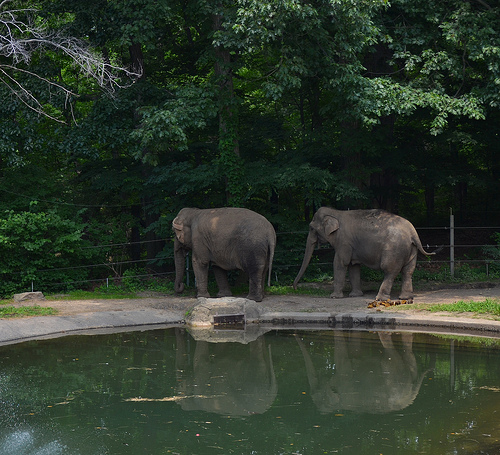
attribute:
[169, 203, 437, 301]
elephants — grey, standing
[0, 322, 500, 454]
pond — calm, murky, small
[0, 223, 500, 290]
fence — short, metal, grey, wire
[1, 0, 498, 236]
trees — green, leafy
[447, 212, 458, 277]
pole — metal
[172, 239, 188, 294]
trunk — down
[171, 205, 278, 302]
elephant — gray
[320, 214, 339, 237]
ears — small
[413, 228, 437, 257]
tail — up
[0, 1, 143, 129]
branches — bare